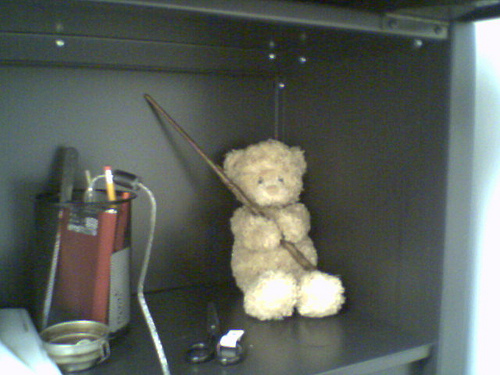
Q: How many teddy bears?
A: 1.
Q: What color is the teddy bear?
A: Brown.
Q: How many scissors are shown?
A: 2.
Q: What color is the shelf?
A: Black.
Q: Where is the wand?
A: In bear's arms.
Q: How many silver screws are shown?
A: 5.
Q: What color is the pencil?
A: Yellow.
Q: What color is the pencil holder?
A: Black.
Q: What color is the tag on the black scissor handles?
A: White.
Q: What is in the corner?
A: A teddy bear holding a stick.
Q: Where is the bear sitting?
A: On a shelf.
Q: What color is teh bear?
A: Beige.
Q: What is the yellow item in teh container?
A: Pencil.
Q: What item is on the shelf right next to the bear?
A: Scissors.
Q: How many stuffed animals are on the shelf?
A: 1.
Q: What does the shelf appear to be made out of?
A: Woodx.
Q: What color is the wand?
A: Brown.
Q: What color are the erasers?
A: Pink.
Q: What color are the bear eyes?
A: Black.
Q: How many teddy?
A: 1.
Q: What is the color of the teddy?
A: Ivory.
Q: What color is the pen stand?
A: Black.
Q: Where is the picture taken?
A: On the bookshelf.